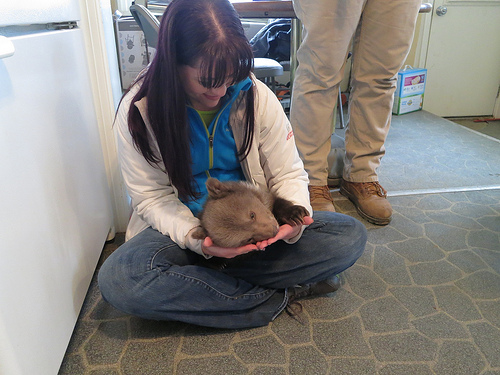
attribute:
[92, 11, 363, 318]
woman — young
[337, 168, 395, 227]
boot — brown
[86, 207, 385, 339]
jeans — blue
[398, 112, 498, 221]
floor — grey, pebbled, tiled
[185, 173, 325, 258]
bear — baby, brown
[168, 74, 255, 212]
fleece — blue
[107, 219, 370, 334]
legs — crossed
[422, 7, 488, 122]
door — closed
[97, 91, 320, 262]
jacket — white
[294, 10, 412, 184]
pants — tan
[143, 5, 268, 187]
hair — long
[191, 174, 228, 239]
ears — round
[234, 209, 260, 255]
eyes — open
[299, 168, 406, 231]
shoes — brown, tan